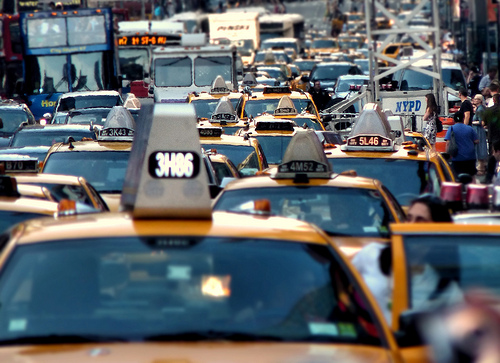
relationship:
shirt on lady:
[351, 246, 459, 321] [347, 187, 467, 328]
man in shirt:
[445, 80, 499, 134] [306, 83, 337, 117]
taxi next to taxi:
[0, 96, 406, 361] [209, 160, 406, 258]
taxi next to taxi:
[209, 160, 406, 258] [312, 99, 459, 216]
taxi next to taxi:
[213, 165, 403, 245] [6, 194, 393, 361]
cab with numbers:
[5, 206, 401, 362] [149, 149, 196, 180]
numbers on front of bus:
[114, 31, 172, 45] [114, 17, 188, 86]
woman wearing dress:
[416, 86, 443, 143] [457, 107, 498, 195]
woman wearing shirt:
[446, 106, 486, 183] [446, 124, 481, 159]